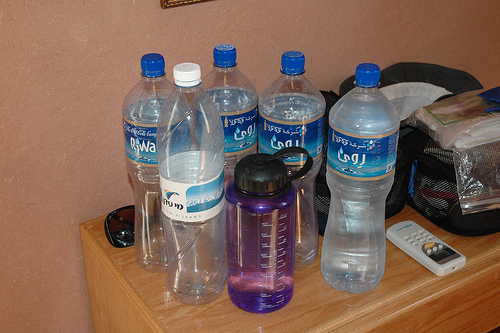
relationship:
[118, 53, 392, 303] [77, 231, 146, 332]
bottles on counter